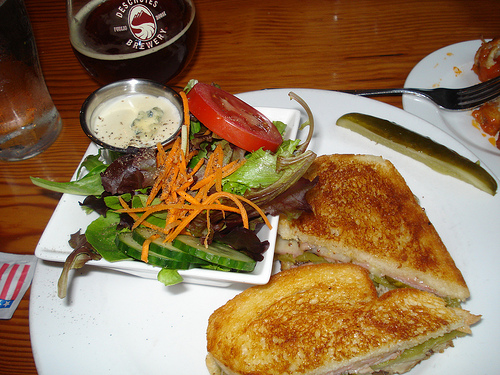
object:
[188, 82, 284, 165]
tomato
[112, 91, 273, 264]
carrots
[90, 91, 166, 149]
dressing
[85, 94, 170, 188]
container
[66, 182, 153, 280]
greens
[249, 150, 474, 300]
sandwich cut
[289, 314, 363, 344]
bread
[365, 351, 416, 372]
meat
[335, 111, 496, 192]
pickle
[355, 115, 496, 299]
plate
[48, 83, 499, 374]
food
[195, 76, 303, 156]
slice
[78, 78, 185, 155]
bowl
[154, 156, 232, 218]
parts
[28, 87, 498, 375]
plate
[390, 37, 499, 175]
plate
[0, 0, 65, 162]
glass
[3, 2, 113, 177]
corner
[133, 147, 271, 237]
strips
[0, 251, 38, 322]
packet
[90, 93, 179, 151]
dip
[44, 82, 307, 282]
salad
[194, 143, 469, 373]
sandwich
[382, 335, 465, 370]
lettuce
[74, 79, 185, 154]
cup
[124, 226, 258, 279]
slices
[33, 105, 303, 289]
plate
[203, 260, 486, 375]
sandwich half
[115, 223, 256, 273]
cucumber slices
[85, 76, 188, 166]
metal dish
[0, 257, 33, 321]
flag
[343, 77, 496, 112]
fork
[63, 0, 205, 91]
glass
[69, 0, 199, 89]
beer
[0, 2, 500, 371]
table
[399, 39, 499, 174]
plate